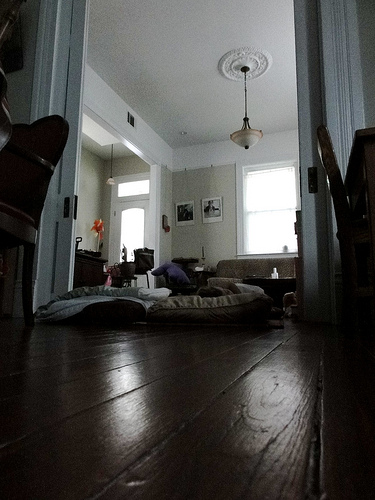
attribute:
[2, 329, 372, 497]
floor boards — polished, wooden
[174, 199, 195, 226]
art — affixed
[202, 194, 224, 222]
print — black, white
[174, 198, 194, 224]
print — black, white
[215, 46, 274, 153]
light fixture — hanging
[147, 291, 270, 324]
pillow — large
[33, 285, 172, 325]
pillow — large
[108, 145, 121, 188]
hanging light — small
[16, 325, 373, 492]
floor — dark brown, wooden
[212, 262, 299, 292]
sofa — beneath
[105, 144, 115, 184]
light — small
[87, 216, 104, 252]
flower — orange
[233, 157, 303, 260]
window — letting in, covered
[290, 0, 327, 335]
door — sliding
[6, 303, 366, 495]
floor — natural wood, glossy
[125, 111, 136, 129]
vent — above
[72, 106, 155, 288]
door frame — wooden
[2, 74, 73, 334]
chair — wood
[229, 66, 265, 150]
light — hanging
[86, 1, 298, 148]
ceiling — white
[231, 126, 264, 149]
shade — glass